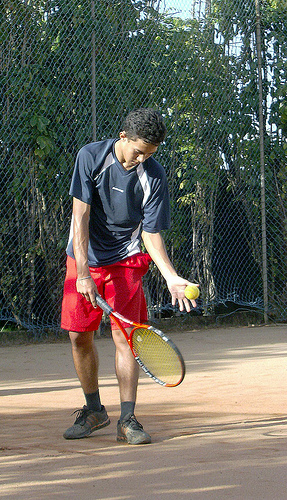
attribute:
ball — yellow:
[185, 285, 199, 300]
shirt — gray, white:
[67, 151, 165, 260]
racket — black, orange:
[94, 297, 194, 395]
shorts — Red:
[71, 248, 144, 327]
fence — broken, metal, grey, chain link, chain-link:
[1, 1, 286, 324]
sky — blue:
[3, 1, 284, 168]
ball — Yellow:
[182, 283, 200, 301]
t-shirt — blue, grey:
[66, 136, 170, 268]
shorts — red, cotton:
[56, 258, 149, 331]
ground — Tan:
[2, 325, 284, 497]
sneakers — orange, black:
[62, 404, 150, 444]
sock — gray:
[117, 398, 137, 422]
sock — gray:
[84, 386, 103, 411]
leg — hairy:
[67, 325, 100, 407]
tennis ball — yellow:
[184, 285, 200, 300]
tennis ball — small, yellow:
[183, 284, 199, 299]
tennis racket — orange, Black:
[86, 289, 187, 388]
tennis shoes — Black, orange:
[62, 403, 151, 450]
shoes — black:
[64, 387, 149, 444]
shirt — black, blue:
[65, 138, 170, 265]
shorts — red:
[60, 251, 151, 330]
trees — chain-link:
[1, 0, 92, 238]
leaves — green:
[100, 14, 283, 310]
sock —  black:
[122, 398, 139, 417]